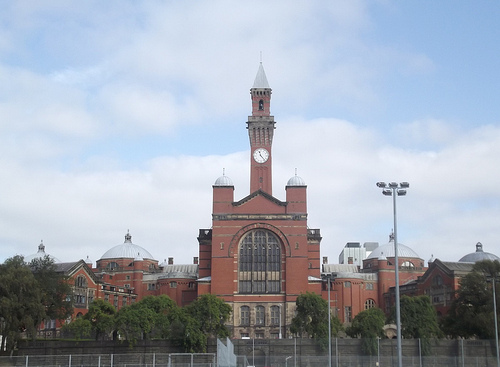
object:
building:
[196, 50, 323, 339]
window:
[235, 220, 287, 295]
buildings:
[361, 231, 498, 337]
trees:
[454, 258, 499, 346]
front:
[0, 222, 428, 277]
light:
[376, 179, 415, 367]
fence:
[1, 351, 499, 366]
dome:
[95, 229, 159, 260]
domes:
[366, 230, 418, 258]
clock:
[252, 147, 271, 165]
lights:
[399, 181, 411, 189]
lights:
[397, 190, 407, 197]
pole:
[391, 203, 405, 362]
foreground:
[1, 335, 500, 366]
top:
[248, 48, 273, 90]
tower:
[243, 48, 278, 191]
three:
[235, 302, 286, 340]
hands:
[260, 155, 265, 161]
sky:
[1, 3, 497, 176]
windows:
[269, 304, 280, 326]